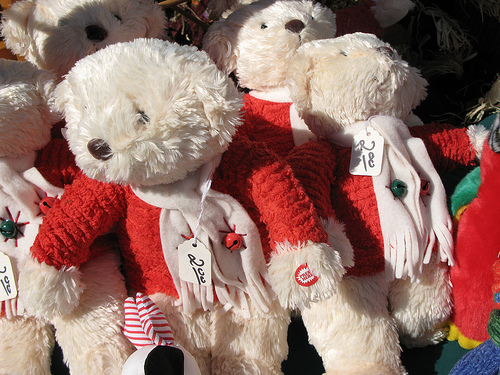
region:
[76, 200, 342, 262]
the teddy bear has red sweater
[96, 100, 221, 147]
the teddybear has white fur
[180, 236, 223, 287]
the tag has 200 written on it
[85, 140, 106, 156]
the nose is black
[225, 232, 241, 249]
the button is red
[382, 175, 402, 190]
the button is green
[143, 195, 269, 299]
the scarf is white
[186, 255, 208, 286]
200 is black in writing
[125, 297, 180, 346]
the material has red and white stripes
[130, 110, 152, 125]
the eye is black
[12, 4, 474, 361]
white and red teddy bears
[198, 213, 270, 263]
teddy bear wearing red bell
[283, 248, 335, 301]
"press here" sticker on paw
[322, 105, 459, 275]
white scarf on bear's neck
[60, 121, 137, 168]
black nose on bear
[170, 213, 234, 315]
two dollar price tag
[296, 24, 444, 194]
price tag on teddy bear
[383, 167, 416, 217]
green jingle bell on scarf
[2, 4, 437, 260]
five stuffed teddy bears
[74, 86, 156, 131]
black eyes on stuffed bear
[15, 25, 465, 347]
toy bears displayed next to each other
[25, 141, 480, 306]
bears wearing red knitted jackets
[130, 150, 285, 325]
bear wearing a white scarf with fringe at ends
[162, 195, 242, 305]
written price on tag attached to scarf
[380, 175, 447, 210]
green and red bells adorning scarf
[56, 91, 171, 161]
eyes and nose marked by black buttons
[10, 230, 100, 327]
white paw sticking out of red sleeve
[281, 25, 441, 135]
bear with head looking upward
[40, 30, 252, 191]
fluffy white head on stuffed animal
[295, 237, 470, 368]
unclothed legs of toy bear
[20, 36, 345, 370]
a teddy bear dressed in red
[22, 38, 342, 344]
a 2 dollar toy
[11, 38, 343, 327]
a bear wearing an ascot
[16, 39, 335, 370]
a white scarf on a bear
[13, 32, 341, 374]
a white scarf on a teddy bear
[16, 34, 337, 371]
a bear looking longingly to his right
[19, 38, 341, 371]
a dark eyed guy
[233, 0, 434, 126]
two bears looking skyward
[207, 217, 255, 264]
a red bell as a stick pin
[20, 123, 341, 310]
a knitted sweater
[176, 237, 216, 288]
white paper price tag with 2.00 written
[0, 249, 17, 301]
white paper price tag with 2.00 written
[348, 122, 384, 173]
white paper price tag with 2.00 written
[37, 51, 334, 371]
white fluffy teddy bear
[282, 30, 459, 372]
white fluffy teddy bear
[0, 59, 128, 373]
white fluffy teddy bear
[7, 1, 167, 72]
white fluffy teddy bear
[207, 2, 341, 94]
white fluffy teddy bear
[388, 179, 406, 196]
green metal jingle bell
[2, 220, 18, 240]
green metal jingle bell